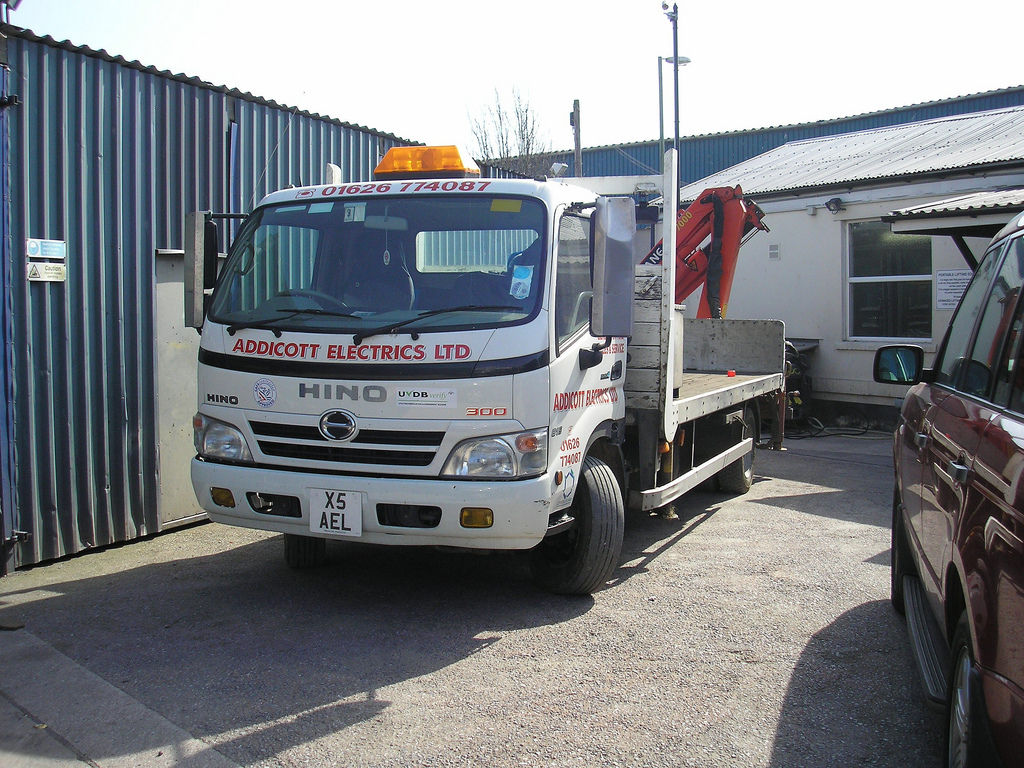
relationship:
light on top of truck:
[373, 145, 482, 180] [182, 141, 790, 595]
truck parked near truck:
[863, 206, 1021, 764] [182, 141, 790, 595]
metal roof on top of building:
[679, 102, 1021, 200] [640, 96, 1021, 410]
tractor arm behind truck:
[633, 180, 770, 315] [182, 141, 790, 595]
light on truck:
[374, 143, 485, 178] [191, 145, 788, 595]